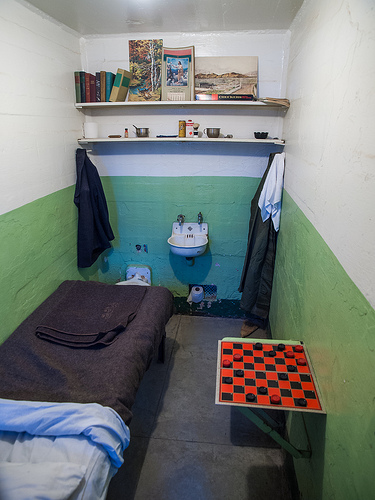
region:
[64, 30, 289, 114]
shelf with books, calendar and pictures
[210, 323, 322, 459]
checkers set on black and red board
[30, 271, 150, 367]
folded black blanket with printing on corner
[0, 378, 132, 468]
blue sheet turned down on bed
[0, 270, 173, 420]
dark grey blanket covering bed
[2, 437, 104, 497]
light blue pillow case and fitted sheet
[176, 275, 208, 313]
roll of toilet paper on short rod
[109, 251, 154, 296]
edge of white toilet at end of bed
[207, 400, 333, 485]
metal support for folding green table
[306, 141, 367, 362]
white paint on top and green on bottom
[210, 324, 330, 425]
the board is checkerd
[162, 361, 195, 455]
the floor is gray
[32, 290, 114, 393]
the blankets are gray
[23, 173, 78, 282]
the wall is white and green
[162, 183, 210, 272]
the sink is white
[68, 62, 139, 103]
the books are shelved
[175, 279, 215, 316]
the paper is white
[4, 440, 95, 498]
the pillow is white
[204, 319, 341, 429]
the board is red and black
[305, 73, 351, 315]
the wall is painted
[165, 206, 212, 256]
WHITE EMPTY SINK ATTACHED TO WALL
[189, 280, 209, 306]
ROLL OF TOILET PAPER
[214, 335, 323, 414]
CHECKERBOARD WITH CHECKERS IN PLAY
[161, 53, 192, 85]
PICTURE OF THE LORD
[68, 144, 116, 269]
COAT HANGING ON THE WALL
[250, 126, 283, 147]
ASHTRAY SITTING ON THE SHELF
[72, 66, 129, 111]
EIGHT BOOKS SITTING ON SHELF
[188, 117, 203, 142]
SHAVING BRUSH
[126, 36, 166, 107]
PICTURE OF NATURE WITH MANY COLORS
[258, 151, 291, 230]
WHITE TOWEL HANGING ON WALL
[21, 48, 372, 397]
This is a photo of a jail cell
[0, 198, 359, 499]
There is a checker board in the room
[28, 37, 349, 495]
The walls are green and white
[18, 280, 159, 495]
There is a made bed in the room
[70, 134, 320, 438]
There is a white sink in the room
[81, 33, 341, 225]
There are shelves above the sink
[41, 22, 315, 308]
There are shelves above the white sink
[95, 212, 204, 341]
There is a toilet in the room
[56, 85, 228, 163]
There is toilet paper on the bottom shelf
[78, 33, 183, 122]
There are books on the top shelf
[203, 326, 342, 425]
checkerboard is red and black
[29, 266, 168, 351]
towel on bed is black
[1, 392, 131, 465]
sheet is white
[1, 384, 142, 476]
sheet will be used for suicide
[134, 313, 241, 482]
floor will reflect hanged mans shadow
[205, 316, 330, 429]
feet will touch checkerboard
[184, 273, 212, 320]
toilet paper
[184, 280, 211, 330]
toilet paper is white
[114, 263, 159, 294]
toilet is in front of bed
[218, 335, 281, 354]
checker is black